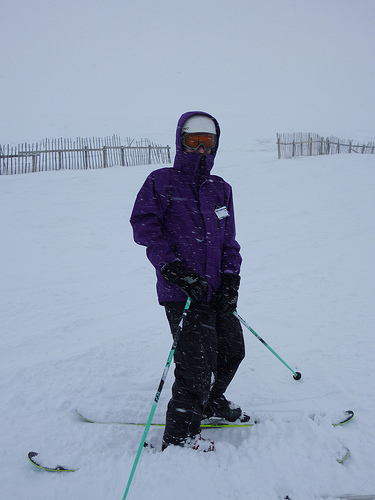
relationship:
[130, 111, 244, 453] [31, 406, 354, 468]
person wearing skis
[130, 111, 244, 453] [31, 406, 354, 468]
person on skis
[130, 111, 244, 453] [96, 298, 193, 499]
person holding ski pole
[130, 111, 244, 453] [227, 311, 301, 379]
person holding ski pole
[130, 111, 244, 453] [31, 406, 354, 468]
person standing on skis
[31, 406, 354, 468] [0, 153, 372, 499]
skis under snow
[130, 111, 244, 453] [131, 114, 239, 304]
person wearing jacket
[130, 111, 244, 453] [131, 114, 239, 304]
person wearing a jacket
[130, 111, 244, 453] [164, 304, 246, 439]
person wearing pants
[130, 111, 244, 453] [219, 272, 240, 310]
person wearing glove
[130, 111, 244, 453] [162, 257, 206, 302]
person wearing glove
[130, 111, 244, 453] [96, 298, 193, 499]
person holding pole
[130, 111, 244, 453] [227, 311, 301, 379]
person holding pole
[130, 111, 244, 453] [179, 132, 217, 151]
person wearing goggles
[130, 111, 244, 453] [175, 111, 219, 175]
person wearing hood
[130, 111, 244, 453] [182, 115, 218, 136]
person wearing white helmet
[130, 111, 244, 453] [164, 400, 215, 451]
person wearing boot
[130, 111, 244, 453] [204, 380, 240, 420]
person wearing boot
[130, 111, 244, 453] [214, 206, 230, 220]
person wearing tag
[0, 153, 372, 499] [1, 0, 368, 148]
snow in sky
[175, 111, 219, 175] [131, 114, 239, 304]
hood on jacket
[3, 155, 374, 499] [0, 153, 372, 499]
ground covered in snow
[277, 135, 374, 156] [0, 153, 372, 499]
fence in snow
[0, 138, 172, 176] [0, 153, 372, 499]
fence in snow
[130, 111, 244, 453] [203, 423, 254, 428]
person using green ski